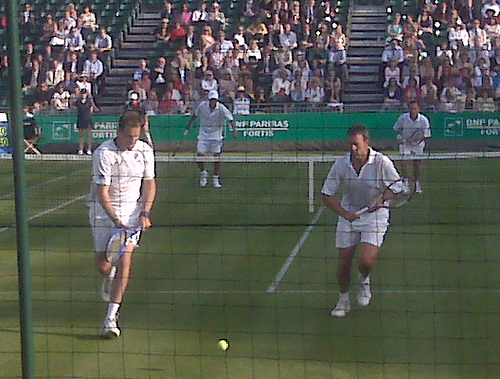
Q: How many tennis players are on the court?
A: 4.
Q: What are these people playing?
A: Mixed doubles tennis.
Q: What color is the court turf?
A: Green.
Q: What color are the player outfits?
A: White.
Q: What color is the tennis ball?
A: Yellow.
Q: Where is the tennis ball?
A: On the ground.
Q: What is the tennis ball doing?
A: Rolling away.